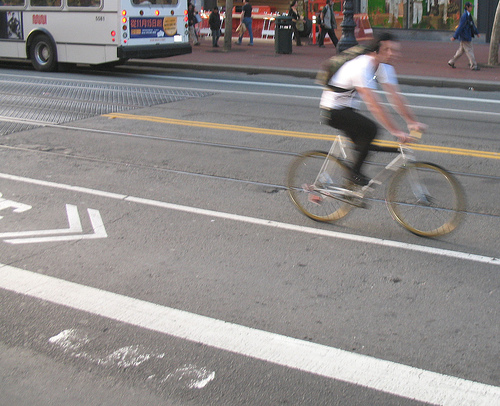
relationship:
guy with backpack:
[315, 34, 427, 190] [310, 36, 381, 97]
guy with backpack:
[315, 28, 430, 190] [310, 36, 381, 97]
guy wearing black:
[315, 28, 430, 190] [315, 103, 384, 174]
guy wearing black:
[315, 34, 427, 190] [315, 103, 384, 174]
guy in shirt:
[315, 34, 427, 190] [317, 52, 401, 113]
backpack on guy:
[310, 36, 381, 97] [315, 34, 427, 190]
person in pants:
[445, 2, 488, 72] [444, 36, 481, 70]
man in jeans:
[234, 0, 257, 48] [237, 15, 256, 49]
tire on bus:
[25, 25, 59, 75] [1, 0, 200, 75]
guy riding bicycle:
[315, 34, 427, 190] [283, 119, 472, 240]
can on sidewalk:
[270, 15, 300, 58] [186, 39, 500, 90]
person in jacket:
[445, 2, 488, 72] [450, 12, 482, 46]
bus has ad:
[1, 0, 200, 75] [127, 15, 183, 41]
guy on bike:
[315, 34, 427, 190] [283, 119, 472, 240]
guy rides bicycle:
[315, 34, 427, 190] [284, 119, 472, 241]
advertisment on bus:
[127, 15, 183, 41] [1, 0, 200, 75]